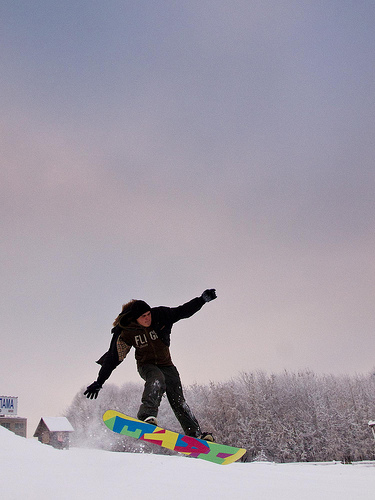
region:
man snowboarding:
[88, 278, 250, 468]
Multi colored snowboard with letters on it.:
[96, 406, 249, 470]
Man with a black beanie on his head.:
[124, 296, 156, 332]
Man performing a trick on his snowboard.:
[76, 273, 306, 473]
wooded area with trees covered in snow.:
[216, 370, 374, 464]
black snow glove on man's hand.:
[195, 284, 221, 304]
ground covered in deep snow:
[64, 455, 191, 498]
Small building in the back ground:
[33, 411, 74, 457]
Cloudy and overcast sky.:
[250, 264, 351, 351]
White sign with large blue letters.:
[1, 390, 21, 422]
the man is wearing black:
[37, 233, 221, 463]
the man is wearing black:
[92, 285, 212, 424]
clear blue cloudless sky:
[81, 6, 168, 74]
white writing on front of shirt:
[131, 327, 157, 347]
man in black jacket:
[88, 278, 242, 400]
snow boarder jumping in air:
[69, 286, 284, 479]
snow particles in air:
[75, 416, 103, 443]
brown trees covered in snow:
[254, 370, 343, 447]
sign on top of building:
[0, 394, 22, 419]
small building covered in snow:
[28, 410, 75, 452]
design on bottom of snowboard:
[107, 432, 237, 461]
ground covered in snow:
[43, 466, 135, 498]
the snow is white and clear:
[108, 471, 147, 495]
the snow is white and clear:
[62, 435, 132, 492]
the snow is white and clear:
[60, 430, 97, 469]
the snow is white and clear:
[71, 455, 109, 493]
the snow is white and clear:
[94, 454, 138, 490]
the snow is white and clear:
[73, 402, 164, 497]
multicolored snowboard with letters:
[100, 394, 239, 477]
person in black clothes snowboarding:
[92, 283, 222, 461]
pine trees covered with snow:
[212, 376, 353, 460]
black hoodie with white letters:
[122, 329, 172, 360]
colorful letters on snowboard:
[123, 418, 222, 466]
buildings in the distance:
[4, 394, 64, 458]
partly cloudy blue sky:
[98, 113, 287, 268]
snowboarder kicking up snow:
[76, 419, 177, 485]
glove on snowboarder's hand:
[71, 371, 123, 414]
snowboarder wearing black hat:
[110, 291, 164, 329]